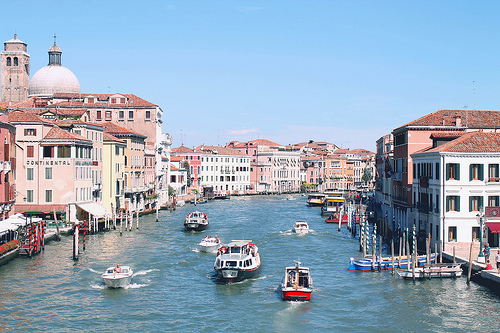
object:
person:
[485, 260, 492, 270]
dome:
[28, 33, 81, 98]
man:
[113, 264, 122, 274]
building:
[0, 112, 103, 225]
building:
[157, 154, 169, 205]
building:
[170, 163, 188, 197]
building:
[171, 143, 202, 195]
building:
[194, 143, 251, 195]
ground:
[392, 166, 418, 206]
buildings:
[250, 160, 273, 192]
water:
[225, 202, 275, 227]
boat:
[197, 232, 221, 252]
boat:
[184, 210, 209, 231]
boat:
[101, 264, 134, 289]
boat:
[348, 252, 439, 271]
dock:
[442, 243, 500, 283]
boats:
[394, 263, 464, 279]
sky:
[99, 11, 417, 62]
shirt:
[116, 267, 121, 272]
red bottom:
[283, 291, 311, 299]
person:
[483, 242, 490, 262]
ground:
[360, 149, 424, 198]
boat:
[293, 220, 309, 234]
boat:
[213, 240, 261, 285]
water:
[101, 317, 141, 333]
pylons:
[26, 221, 44, 257]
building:
[101, 131, 126, 218]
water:
[287, 202, 299, 213]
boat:
[281, 256, 314, 302]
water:
[165, 288, 223, 313]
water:
[143, 234, 173, 264]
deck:
[459, 244, 474, 255]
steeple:
[28, 33, 82, 99]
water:
[317, 301, 465, 326]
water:
[5, 304, 56, 325]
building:
[97, 121, 147, 212]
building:
[144, 140, 157, 211]